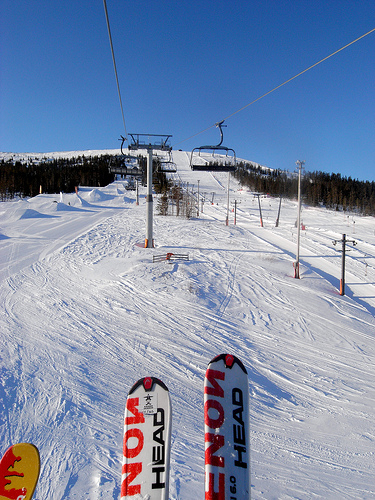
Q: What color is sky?
A: Blue.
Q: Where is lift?
A: Ski slope.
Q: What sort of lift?
A: Chair lift.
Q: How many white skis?
A: Two.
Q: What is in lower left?
A: Yellow ski.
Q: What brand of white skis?
A: Head.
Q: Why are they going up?
A: To ski down.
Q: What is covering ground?
A: Snow.